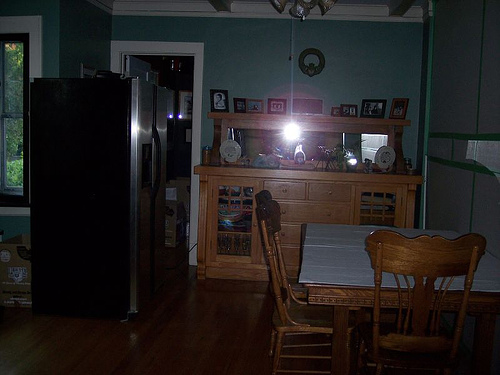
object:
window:
[0, 38, 30, 201]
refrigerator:
[30, 71, 172, 321]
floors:
[0, 276, 273, 375]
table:
[299, 220, 499, 317]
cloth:
[297, 222, 499, 293]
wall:
[110, 15, 420, 166]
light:
[277, 119, 303, 140]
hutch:
[191, 108, 420, 293]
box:
[0, 230, 34, 307]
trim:
[0, 15, 39, 37]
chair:
[360, 227, 488, 375]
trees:
[3, 40, 24, 187]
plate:
[217, 136, 244, 164]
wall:
[0, 9, 61, 79]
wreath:
[296, 48, 327, 79]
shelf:
[206, 110, 411, 136]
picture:
[385, 96, 412, 119]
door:
[202, 176, 267, 271]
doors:
[126, 75, 158, 324]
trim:
[106, 41, 205, 55]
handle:
[140, 144, 155, 185]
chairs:
[256, 200, 375, 375]